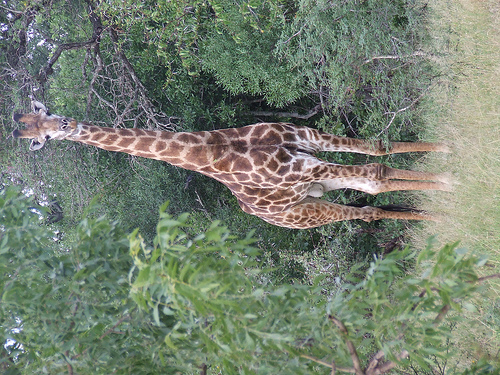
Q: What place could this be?
A: It is a field.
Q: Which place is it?
A: It is a field.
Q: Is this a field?
A: Yes, it is a field.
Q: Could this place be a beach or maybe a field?
A: It is a field.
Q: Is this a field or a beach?
A: It is a field.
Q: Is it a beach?
A: No, it is a field.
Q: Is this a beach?
A: No, it is a field.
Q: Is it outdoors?
A: Yes, it is outdoors.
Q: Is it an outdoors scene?
A: Yes, it is outdoors.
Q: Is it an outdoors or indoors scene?
A: It is outdoors.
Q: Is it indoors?
A: No, it is outdoors.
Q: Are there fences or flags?
A: No, there are no fences or flags.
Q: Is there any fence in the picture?
A: No, there are no fences.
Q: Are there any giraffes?
A: Yes, there is a giraffe.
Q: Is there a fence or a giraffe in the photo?
A: Yes, there is a giraffe.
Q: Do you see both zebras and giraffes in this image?
A: No, there is a giraffe but no zebras.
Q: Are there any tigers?
A: No, there are no tigers.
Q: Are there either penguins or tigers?
A: No, there are no tigers or penguins.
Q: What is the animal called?
A: The animal is a giraffe.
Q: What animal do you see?
A: The animal is a giraffe.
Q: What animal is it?
A: The animal is a giraffe.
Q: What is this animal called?
A: This is a giraffe.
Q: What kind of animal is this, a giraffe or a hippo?
A: This is a giraffe.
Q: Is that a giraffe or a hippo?
A: That is a giraffe.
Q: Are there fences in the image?
A: No, there are no fences.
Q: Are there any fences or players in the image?
A: No, there are no fences or players.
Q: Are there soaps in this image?
A: No, there are no soaps.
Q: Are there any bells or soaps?
A: No, there are no soaps or bells.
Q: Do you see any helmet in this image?
A: No, there are no helmets.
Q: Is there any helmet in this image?
A: No, there are no helmets.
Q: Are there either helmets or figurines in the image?
A: No, there are no helmets or figurines.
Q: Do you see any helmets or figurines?
A: No, there are no helmets or figurines.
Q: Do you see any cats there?
A: No, there are no cats.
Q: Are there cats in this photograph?
A: No, there are no cats.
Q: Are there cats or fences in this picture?
A: No, there are no cats or fences.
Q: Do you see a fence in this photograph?
A: No, there are no fences.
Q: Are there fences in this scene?
A: No, there are no fences.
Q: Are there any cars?
A: No, there are no cars.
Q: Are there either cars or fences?
A: No, there are no cars or fences.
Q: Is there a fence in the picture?
A: No, there are no fences.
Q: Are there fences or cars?
A: No, there are no fences or cars.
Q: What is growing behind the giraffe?
A: The trees are growing behind the giraffe.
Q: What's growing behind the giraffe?
A: The trees are growing behind the giraffe.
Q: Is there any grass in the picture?
A: Yes, there is grass.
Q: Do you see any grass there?
A: Yes, there is grass.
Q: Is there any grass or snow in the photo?
A: Yes, there is grass.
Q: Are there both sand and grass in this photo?
A: No, there is grass but no sand.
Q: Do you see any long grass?
A: Yes, there is long grass.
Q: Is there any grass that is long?
A: Yes, there is grass that is long.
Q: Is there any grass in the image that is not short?
A: Yes, there is long grass.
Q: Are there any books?
A: No, there are no books.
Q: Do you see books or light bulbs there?
A: No, there are no books or light bulbs.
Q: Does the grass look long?
A: Yes, the grass is long.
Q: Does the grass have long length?
A: Yes, the grass is long.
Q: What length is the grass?
A: The grass is long.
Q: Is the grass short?
A: No, the grass is long.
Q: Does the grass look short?
A: No, the grass is long.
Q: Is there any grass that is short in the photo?
A: No, there is grass but it is long.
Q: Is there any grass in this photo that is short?
A: No, there is grass but it is long.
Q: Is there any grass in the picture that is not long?
A: No, there is grass but it is long.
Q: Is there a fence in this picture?
A: No, there are no fences.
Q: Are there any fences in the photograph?
A: No, there are no fences.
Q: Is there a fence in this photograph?
A: No, there are no fences.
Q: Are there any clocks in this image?
A: No, there are no clocks.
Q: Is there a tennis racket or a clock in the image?
A: No, there are no clocks or rackets.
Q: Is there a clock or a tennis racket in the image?
A: No, there are no clocks or rackets.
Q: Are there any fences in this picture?
A: No, there are no fences.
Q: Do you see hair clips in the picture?
A: No, there are no hair clips.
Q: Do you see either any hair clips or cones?
A: No, there are no hair clips or cones.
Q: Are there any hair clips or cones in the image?
A: No, there are no hair clips or cones.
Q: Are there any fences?
A: No, there are no fences.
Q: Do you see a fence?
A: No, there are no fences.